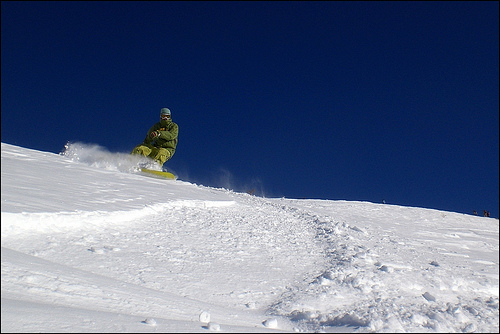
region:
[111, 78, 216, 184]
man snowboarding in the snow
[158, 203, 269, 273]
snow on the ground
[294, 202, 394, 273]
tracks in the snow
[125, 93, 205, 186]
man wearing the color green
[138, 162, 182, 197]
snowboard on the ground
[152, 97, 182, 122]
goggles on the man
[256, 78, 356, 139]
blue sky behind the man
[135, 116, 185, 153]
green outfit on man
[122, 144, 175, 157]
green pants on man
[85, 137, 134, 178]
snow next to the person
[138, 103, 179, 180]
a snowboarder snowboaring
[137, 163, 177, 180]
a lime green long snowboard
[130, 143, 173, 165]
a lime green pair of ski pants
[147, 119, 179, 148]
a lime green winter jacket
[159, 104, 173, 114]
a lime green winter hat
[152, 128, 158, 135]
a winter glove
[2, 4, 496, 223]
a dark blue sky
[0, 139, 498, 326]
a snowy slope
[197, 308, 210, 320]
white snow clump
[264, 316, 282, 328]
white snow clump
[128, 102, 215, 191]
snowboarder on yellow board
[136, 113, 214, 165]
snowboarder has green jacket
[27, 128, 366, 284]
snow is white powder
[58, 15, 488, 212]
sky is clear deep blue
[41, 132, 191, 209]
snow dust behind snowboarder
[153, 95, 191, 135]
snoawboarder wearing grey cap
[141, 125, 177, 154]
snowboarder wearing ski gloves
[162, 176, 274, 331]
trail in the snow from snowboarder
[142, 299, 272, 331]
chunks of ice and snow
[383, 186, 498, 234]
people far in the distance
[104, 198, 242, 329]
the snow is white and clear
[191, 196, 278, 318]
the snow is white and clear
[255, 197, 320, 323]
the snow is white and clear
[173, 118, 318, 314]
the snow is white and clear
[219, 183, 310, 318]
the snow is white and clear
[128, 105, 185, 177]
a person snowboarding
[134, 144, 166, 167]
a lime green pair of snowboarding pants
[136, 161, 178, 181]
a lime green snowboard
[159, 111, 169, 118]
a pair of snowboarding goggles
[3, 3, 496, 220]
a deep blue sky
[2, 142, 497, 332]
a white snowy slope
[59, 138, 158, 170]
snow spraying in front of man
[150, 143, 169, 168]
the leg of a man